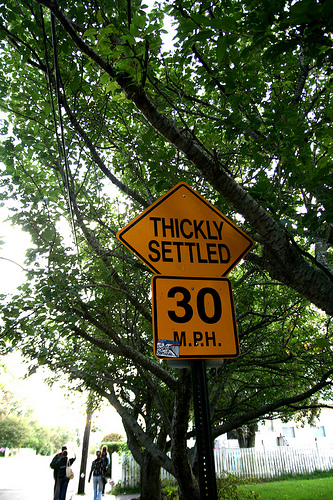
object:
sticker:
[156, 339, 180, 359]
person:
[88, 451, 107, 500]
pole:
[78, 389, 93, 496]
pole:
[189, 357, 219, 498]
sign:
[151, 274, 239, 361]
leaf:
[161, 51, 170, 56]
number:
[167, 285, 193, 323]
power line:
[50, 3, 81, 266]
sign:
[115, 182, 254, 275]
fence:
[110, 451, 331, 493]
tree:
[0, 203, 331, 496]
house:
[186, 389, 333, 472]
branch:
[43, 2, 331, 310]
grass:
[165, 474, 331, 499]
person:
[54, 451, 77, 500]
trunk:
[139, 453, 163, 497]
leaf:
[35, 279, 39, 282]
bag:
[66, 466, 74, 480]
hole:
[203, 457, 205, 460]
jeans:
[92, 476, 103, 499]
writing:
[149, 217, 162, 237]